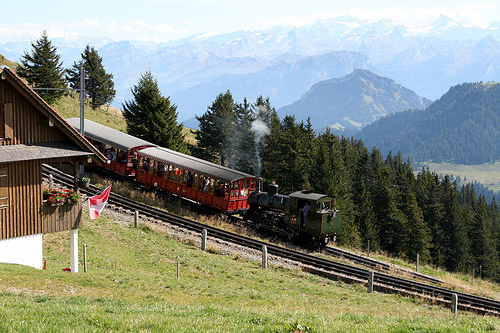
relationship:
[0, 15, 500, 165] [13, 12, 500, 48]
mountains have snow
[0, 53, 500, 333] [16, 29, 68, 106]
hill has a tree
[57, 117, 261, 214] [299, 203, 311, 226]
train has a conductor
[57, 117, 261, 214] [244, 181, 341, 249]
train has an engine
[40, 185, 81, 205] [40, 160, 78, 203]
flowers are in window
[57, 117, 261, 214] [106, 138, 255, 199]
train for passengers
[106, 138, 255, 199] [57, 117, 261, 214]
passengers are in train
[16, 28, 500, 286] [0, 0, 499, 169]
trees are in distance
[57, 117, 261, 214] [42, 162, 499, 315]
train coming down train tracks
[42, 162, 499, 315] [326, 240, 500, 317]
train tracks have an empty section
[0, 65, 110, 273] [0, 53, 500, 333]
house on hill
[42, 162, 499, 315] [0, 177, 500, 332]
tracks are near a green area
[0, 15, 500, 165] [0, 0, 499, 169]
mountains are in distance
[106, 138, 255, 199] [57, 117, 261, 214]
passengers on a train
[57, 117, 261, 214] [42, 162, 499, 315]
train on train tracks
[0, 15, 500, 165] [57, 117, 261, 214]
mountains are behind train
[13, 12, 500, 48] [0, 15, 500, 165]
snow on mountains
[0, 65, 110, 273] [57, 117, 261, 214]
house near train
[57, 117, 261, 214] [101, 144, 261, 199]
train has windows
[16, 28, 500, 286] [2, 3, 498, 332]
trees in landscape